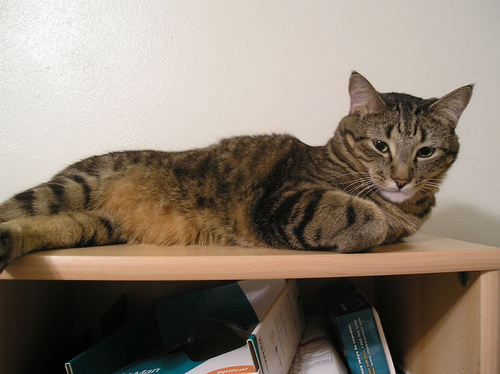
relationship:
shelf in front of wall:
[0, 226, 498, 373] [2, 0, 498, 244]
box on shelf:
[319, 279, 400, 373] [0, 226, 498, 373]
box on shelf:
[66, 280, 307, 373] [0, 226, 498, 373]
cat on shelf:
[0, 70, 475, 272] [0, 226, 498, 373]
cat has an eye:
[0, 70, 475, 272] [369, 137, 392, 156]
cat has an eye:
[0, 70, 475, 272] [416, 144, 437, 161]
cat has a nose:
[0, 70, 475, 272] [393, 177, 409, 191]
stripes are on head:
[395, 97, 404, 138] [334, 71, 474, 204]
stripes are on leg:
[52, 181, 69, 211] [267, 186, 383, 253]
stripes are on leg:
[52, 181, 69, 211] [2, 175, 101, 218]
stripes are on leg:
[52, 181, 69, 211] [2, 211, 114, 272]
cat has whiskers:
[0, 70, 475, 272] [335, 173, 394, 204]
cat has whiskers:
[0, 70, 475, 272] [415, 178, 469, 206]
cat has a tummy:
[0, 70, 475, 272] [114, 183, 198, 247]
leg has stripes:
[2, 175, 101, 218] [52, 181, 69, 211]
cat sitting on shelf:
[0, 70, 475, 272] [0, 226, 498, 373]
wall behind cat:
[2, 0, 498, 244] [0, 70, 475, 272]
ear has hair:
[347, 72, 386, 116] [356, 83, 367, 108]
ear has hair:
[434, 84, 473, 129] [442, 102, 457, 116]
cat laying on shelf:
[0, 70, 475, 272] [0, 226, 498, 373]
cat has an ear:
[0, 70, 475, 272] [347, 72, 386, 116]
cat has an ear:
[0, 70, 475, 272] [434, 84, 473, 129]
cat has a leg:
[0, 70, 475, 272] [2, 175, 101, 218]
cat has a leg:
[0, 70, 475, 272] [2, 211, 114, 272]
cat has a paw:
[0, 70, 475, 272] [0, 227, 12, 274]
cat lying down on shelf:
[0, 70, 475, 272] [0, 226, 498, 373]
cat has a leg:
[0, 70, 475, 272] [267, 186, 383, 253]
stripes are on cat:
[395, 97, 404, 138] [0, 70, 475, 272]